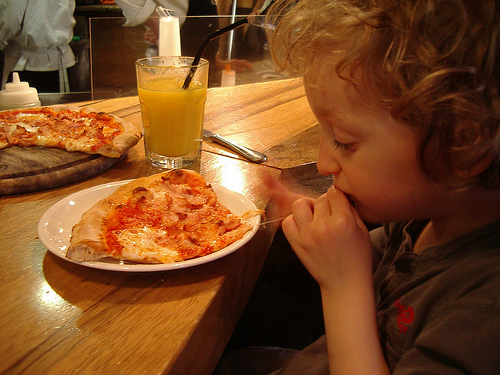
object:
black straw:
[183, 19, 248, 88]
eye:
[332, 130, 359, 151]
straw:
[178, 25, 258, 89]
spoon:
[202, 127, 272, 165]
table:
[0, 72, 315, 373]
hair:
[246, 0, 500, 191]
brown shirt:
[270, 220, 499, 375]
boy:
[255, 0, 500, 375]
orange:
[138, 81, 208, 157]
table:
[4, 271, 149, 373]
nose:
[317, 128, 342, 177]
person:
[0, 0, 77, 93]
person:
[113, 0, 191, 47]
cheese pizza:
[63, 165, 255, 265]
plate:
[36, 177, 263, 273]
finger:
[290, 198, 314, 224]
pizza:
[0, 104, 144, 161]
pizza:
[63, 166, 254, 264]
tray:
[0, 130, 124, 192]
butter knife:
[197, 128, 272, 164]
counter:
[3, 77, 308, 374]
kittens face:
[63, 162, 254, 273]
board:
[1, 149, 91, 195]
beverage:
[137, 77, 207, 158]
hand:
[281, 185, 375, 285]